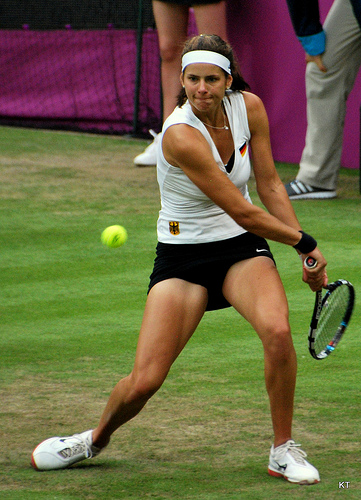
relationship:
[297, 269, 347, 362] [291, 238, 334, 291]
racket in hands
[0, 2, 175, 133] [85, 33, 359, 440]
net behind player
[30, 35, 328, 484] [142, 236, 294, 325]
player has shorts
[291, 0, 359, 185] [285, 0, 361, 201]
pants on leg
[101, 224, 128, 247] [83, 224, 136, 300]
ball in air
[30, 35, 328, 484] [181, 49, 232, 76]
player wearing head band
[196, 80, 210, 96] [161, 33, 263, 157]
nose of a woman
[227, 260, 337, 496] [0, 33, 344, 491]
leg of a woman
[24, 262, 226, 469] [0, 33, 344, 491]
leg of a woman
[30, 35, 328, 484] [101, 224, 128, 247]
player playing ball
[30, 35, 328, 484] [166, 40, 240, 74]
player wearing headband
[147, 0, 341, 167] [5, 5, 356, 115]
persons standing in background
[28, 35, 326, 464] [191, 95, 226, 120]
player has neck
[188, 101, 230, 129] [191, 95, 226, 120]
necklace around neck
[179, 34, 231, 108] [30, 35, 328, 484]
head of player